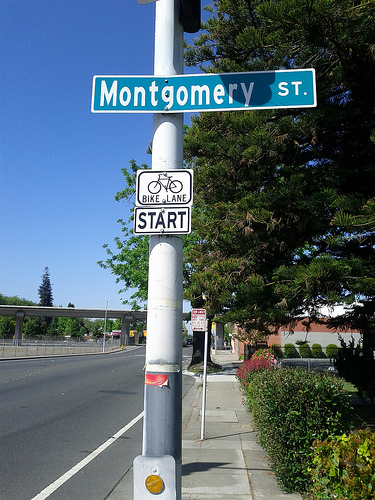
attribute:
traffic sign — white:
[133, 208, 190, 234]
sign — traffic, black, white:
[135, 168, 193, 205]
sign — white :
[191, 306, 206, 334]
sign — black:
[134, 211, 194, 236]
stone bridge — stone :
[6, 300, 147, 325]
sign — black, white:
[129, 202, 194, 236]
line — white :
[30, 410, 143, 498]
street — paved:
[7, 393, 117, 446]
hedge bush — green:
[248, 366, 356, 489]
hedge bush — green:
[324, 342, 338, 355]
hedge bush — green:
[282, 341, 297, 356]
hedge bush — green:
[268, 342, 281, 357]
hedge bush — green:
[303, 427, 373, 499]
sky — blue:
[2, 1, 90, 254]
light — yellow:
[144, 475, 168, 494]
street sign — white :
[89, 67, 323, 118]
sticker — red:
[81, 60, 308, 148]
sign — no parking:
[136, 175, 181, 241]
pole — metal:
[137, 0, 180, 493]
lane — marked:
[50, 418, 110, 497]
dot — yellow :
[143, 471, 168, 496]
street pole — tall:
[133, 7, 189, 499]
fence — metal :
[7, 337, 121, 355]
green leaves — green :
[195, 120, 306, 304]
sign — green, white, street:
[90, 68, 317, 113]